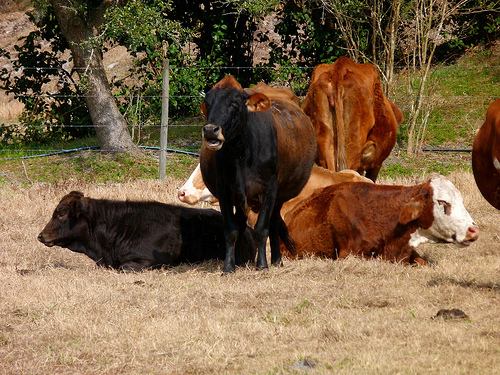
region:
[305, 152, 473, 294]
Cow in a field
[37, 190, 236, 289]
Cow in a field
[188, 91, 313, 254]
Cow in a field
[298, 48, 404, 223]
Cow in a field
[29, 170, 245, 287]
Cow in a field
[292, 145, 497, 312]
Cow in a field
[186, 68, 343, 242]
Cow in a field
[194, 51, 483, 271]
Cow in a field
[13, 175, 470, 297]
Cow in a field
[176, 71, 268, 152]
head of a cow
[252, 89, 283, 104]
ear of a cow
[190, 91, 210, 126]
ear of a cow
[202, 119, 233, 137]
nose of a cow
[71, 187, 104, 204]
ear of a cow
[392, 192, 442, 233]
ear of a cow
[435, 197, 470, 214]
eye of a cow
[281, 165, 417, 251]
body of a cow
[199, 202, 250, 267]
leg of a cow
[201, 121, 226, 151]
A cow mooing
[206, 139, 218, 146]
Mouth of cow open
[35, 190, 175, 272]
A heifer lying on the grass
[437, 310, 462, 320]
Cow dropping on the grass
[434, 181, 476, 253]
Cow with white head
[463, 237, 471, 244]
Cow chewing cud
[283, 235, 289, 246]
A black tail hanging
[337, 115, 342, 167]
A cow's tail hanging down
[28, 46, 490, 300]
A herd of cow in a pen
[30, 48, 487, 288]
A herd of cow in a pen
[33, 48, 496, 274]
A herd of cow in a pen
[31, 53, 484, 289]
A herd of cow in a pen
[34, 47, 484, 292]
A herd of cow in a pen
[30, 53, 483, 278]
A herd of cow in a pen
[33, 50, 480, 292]
A herd of cow in a pen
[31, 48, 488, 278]
A herd of cow in a pen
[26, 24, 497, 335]
cows in a pasteur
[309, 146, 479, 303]
brown cow laying down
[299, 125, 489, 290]
brown cow with a white face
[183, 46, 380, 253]
black and brown cow mooing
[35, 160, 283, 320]
a dark brown cow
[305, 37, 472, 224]
rear end of a brown cow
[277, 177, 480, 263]
A cow in a field.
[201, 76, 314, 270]
A cow in a field.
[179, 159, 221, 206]
A cow in a field.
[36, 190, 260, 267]
A cow in a field.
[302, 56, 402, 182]
A cow in a field.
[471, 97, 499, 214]
A cow in a field.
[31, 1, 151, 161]
A tree in a field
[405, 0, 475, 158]
A tree in a field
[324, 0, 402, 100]
A tree in a field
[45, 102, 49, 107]
A leaf on a stem.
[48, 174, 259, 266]
a cow in a field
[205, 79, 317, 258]
a cow in a field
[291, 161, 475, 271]
a cow in a field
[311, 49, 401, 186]
a cow in a field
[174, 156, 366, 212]
a cow in a field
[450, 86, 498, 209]
a cow in a field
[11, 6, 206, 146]
a tree in a field